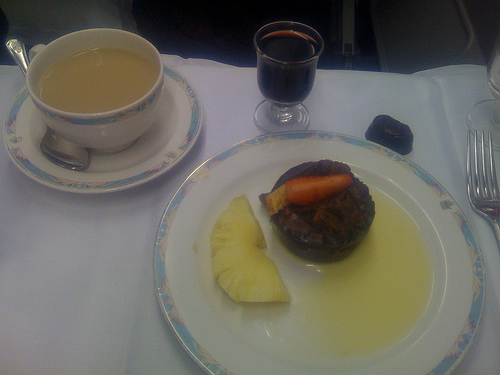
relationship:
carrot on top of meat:
[266, 169, 352, 219] [269, 158, 376, 262]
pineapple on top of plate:
[207, 193, 294, 305] [148, 130, 485, 374]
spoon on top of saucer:
[5, 38, 90, 171] [4, 63, 201, 195]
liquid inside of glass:
[256, 29, 318, 104] [250, 20, 324, 133]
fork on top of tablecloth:
[465, 125, 499, 253] [1, 60, 499, 374]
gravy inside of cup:
[38, 47, 159, 115] [24, 23, 166, 156]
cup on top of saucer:
[24, 23, 166, 156] [4, 63, 201, 195]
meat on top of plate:
[269, 158, 376, 262] [148, 130, 485, 374]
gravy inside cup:
[38, 47, 159, 115] [24, 23, 166, 156]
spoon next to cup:
[5, 38, 90, 171] [24, 23, 166, 156]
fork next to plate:
[465, 125, 499, 253] [148, 130, 485, 374]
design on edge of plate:
[153, 131, 484, 374] [148, 130, 485, 374]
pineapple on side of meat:
[207, 193, 294, 305] [269, 158, 376, 262]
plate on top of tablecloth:
[148, 130, 485, 374] [1, 60, 499, 374]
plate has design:
[148, 130, 485, 374] [153, 131, 484, 374]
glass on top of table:
[250, 20, 324, 133] [0, 62, 499, 373]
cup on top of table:
[24, 23, 166, 156] [0, 62, 499, 373]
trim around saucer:
[5, 64, 202, 192] [4, 63, 201, 195]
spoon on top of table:
[5, 38, 90, 171] [0, 62, 499, 373]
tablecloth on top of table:
[1, 60, 499, 374] [0, 62, 499, 373]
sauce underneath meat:
[275, 179, 434, 359] [269, 158, 376, 262]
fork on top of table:
[465, 125, 499, 253] [0, 62, 499, 373]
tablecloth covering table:
[1, 60, 499, 374] [0, 62, 499, 373]